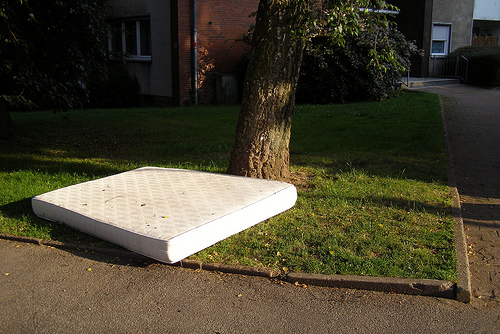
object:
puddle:
[397, 74, 458, 88]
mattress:
[30, 165, 299, 265]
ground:
[5, 84, 499, 334]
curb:
[0, 83, 478, 309]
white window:
[429, 23, 453, 58]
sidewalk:
[0, 234, 499, 334]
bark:
[227, 0, 314, 184]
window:
[104, 15, 154, 62]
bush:
[0, 0, 146, 111]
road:
[1, 230, 500, 333]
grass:
[2, 84, 462, 282]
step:
[407, 76, 453, 87]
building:
[93, 0, 499, 107]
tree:
[0, 0, 137, 114]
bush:
[233, 0, 423, 104]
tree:
[223, 0, 414, 199]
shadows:
[1, 78, 500, 224]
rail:
[397, 52, 411, 88]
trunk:
[225, 1, 309, 181]